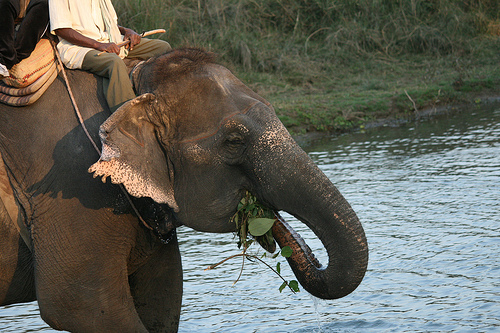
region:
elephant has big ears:
[93, 74, 278, 285]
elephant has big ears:
[76, 18, 271, 216]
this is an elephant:
[53, 74, 250, 330]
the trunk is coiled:
[284, 188, 374, 286]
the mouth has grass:
[236, 200, 270, 244]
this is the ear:
[102, 103, 167, 187]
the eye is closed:
[223, 133, 245, 152]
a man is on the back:
[63, 2, 142, 69]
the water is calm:
[391, 138, 476, 225]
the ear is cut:
[92, 112, 147, 189]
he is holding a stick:
[121, 27, 158, 54]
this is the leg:
[41, 240, 113, 322]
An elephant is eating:
[186, 127, 447, 295]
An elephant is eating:
[181, 36, 330, 288]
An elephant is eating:
[229, 86, 287, 213]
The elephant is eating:
[153, 82, 336, 331]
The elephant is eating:
[206, 126, 305, 310]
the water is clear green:
[405, 258, 465, 302]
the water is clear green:
[429, 211, 469, 271]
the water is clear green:
[355, 272, 447, 327]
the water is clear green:
[397, 238, 439, 318]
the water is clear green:
[367, 258, 431, 295]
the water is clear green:
[435, 267, 453, 305]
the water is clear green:
[407, 248, 435, 262]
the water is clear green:
[402, 261, 434, 285]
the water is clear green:
[373, 241, 395, 262]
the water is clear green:
[395, 251, 457, 279]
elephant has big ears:
[63, 56, 416, 322]